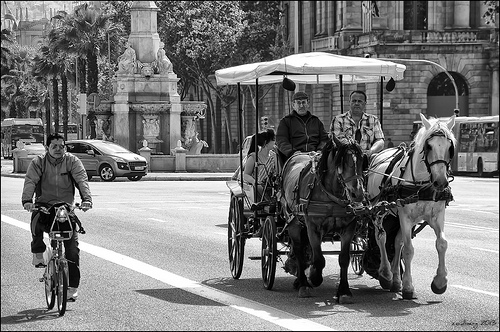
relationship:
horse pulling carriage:
[278, 135, 366, 304] [214, 50, 404, 293]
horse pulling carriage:
[360, 114, 458, 302] [214, 50, 404, 293]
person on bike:
[21, 131, 94, 299] [26, 201, 95, 319]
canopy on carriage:
[214, 49, 406, 86] [214, 50, 404, 293]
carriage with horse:
[214, 50, 404, 293] [278, 135, 366, 304]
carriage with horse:
[214, 50, 404, 293] [360, 114, 458, 302]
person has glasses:
[21, 131, 94, 299] [46, 143, 65, 149]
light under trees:
[75, 92, 92, 139] [1, 1, 279, 155]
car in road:
[58, 137, 148, 181] [1, 174, 498, 330]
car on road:
[58, 137, 148, 181] [1, 174, 498, 330]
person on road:
[21, 131, 94, 299] [1, 174, 498, 330]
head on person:
[45, 134, 66, 160] [21, 131, 94, 299]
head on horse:
[320, 133, 366, 212] [278, 135, 366, 304]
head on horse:
[416, 113, 459, 193] [360, 114, 458, 302]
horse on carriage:
[278, 135, 366, 304] [214, 50, 404, 293]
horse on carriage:
[360, 114, 458, 302] [214, 50, 404, 293]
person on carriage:
[275, 92, 328, 162] [214, 50, 404, 293]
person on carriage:
[330, 91, 384, 157] [214, 50, 404, 293]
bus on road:
[411, 115, 499, 177] [1, 174, 498, 330]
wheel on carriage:
[225, 193, 247, 280] [214, 50, 404, 293]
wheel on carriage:
[260, 215, 279, 287] [214, 50, 404, 293]